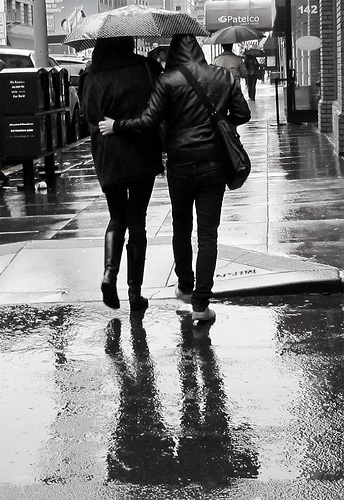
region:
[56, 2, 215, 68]
an umbrella over their heads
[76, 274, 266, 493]
shadows in the wet road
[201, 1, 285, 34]
an awning on the building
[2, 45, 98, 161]
cars parked on the street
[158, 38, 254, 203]
a bag over the person's shoulder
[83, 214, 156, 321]
a pair of boots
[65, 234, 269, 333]
two people stepping onto the sidewalk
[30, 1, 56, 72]
a pole on the sidewalk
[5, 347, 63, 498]
a puddle of water in the street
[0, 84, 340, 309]
a wet sidewalk in the rain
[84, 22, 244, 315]
two people under umbrella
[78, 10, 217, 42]
umbrella has striped pattern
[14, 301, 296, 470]
road behind people is soaked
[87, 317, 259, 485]
dark reflection on street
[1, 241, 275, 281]
sidewalk in front of people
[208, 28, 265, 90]
people in front under umbrellas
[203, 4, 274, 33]
awning in foreground with company name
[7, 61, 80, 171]
newspaper boxes left of people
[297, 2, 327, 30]
numbers on wall near awning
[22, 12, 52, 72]
steel pole behind newspaper dispensers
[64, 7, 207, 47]
an open black umbrella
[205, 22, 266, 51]
an open black umbrella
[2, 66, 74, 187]
newspaper sales boxes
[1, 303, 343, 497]
wet street pavement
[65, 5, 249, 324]
two people walking under umbrella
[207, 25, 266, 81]
a person walking under umbrella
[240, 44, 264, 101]
a person walking under umbrella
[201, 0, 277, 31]
a business awning with name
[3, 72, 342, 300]
a wet paved city sidewalk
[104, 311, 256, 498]
reflection of pedestrians in street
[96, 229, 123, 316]
left leather boot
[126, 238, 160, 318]
right leather boot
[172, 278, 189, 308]
left white shoe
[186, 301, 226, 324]
right white shoe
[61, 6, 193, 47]
lined umbrella the couple is holding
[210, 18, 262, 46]
plain umbrella the man is holding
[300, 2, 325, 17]
number 142 in right upper corner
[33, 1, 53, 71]
street light pole on left side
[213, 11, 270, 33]
Patelco sign on right side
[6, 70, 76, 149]
newspaper holders on left side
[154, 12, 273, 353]
This is a person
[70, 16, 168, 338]
This is a person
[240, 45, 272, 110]
This is a person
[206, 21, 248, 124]
This is a person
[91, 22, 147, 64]
Head of a person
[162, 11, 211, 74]
Head of a personHead of a person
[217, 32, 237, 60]
Head of a person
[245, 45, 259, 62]
Head of a person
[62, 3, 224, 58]
This is an umbrella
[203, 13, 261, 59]
This is an umbrella